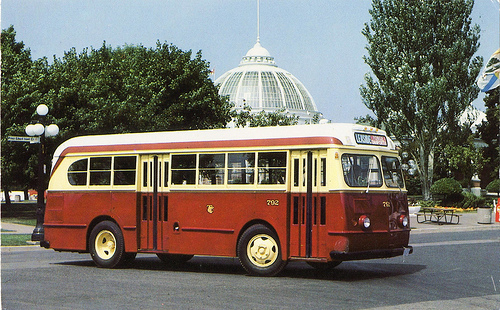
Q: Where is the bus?
A: In the street.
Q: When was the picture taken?
A: During the day.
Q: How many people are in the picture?
A: None.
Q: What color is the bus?
A: Yellow and red.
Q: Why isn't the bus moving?
A: It's parked.